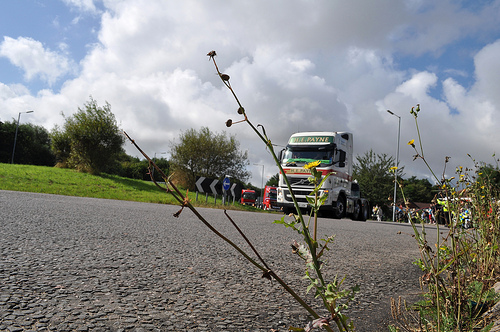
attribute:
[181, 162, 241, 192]
sign — directional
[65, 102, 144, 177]
trees — green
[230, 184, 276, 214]
trucks — red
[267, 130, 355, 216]
cab — white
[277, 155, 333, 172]
stripe — red, green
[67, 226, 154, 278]
concrete — grey, jagged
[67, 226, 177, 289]
concrete — grey, jagged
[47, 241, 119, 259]
street — grey, concrete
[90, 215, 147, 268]
street — concrete, grey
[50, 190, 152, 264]
street — grey, concrete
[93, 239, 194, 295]
street — concrete, grey